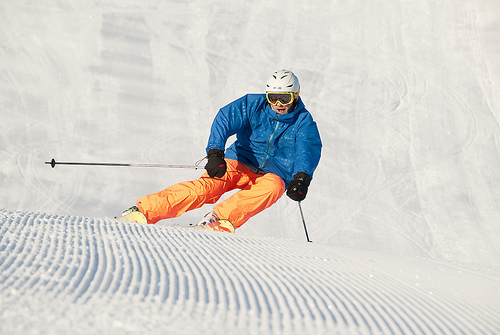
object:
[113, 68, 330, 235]
person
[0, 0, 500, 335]
snow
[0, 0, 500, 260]
hill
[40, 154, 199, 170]
poles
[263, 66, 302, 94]
helmet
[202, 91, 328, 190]
jacket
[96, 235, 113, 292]
ridges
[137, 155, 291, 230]
pants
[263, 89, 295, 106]
goggles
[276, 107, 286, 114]
mouth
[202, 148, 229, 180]
glove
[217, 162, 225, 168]
spot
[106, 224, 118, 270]
tracks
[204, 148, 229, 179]
hand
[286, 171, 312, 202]
glove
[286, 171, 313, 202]
hand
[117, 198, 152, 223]
foot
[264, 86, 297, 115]
face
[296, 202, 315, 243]
ski pole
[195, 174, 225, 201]
knee